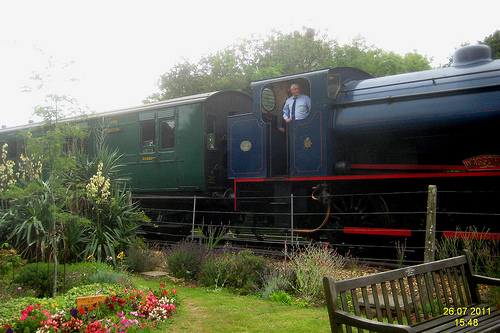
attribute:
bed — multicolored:
[0, 267, 185, 331]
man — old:
[279, 79, 314, 178]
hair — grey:
[290, 81, 299, 89]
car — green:
[2, 85, 231, 252]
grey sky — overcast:
[25, 20, 160, 61]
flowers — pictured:
[136, 285, 178, 323]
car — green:
[3, 66, 485, 252]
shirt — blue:
[282, 98, 314, 123]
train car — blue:
[231, 37, 498, 253]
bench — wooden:
[309, 244, 497, 331]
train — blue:
[0, 45, 498, 273]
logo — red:
[460, 155, 499, 172]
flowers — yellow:
[83, 160, 115, 210]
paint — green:
[165, 104, 205, 183]